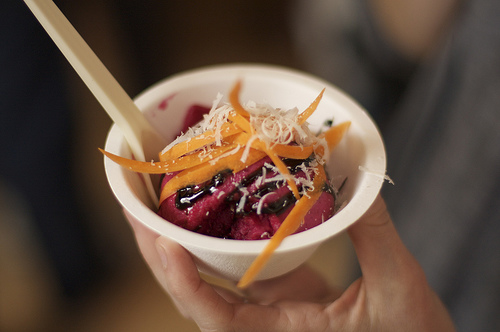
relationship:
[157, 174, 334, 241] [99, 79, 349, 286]
meat under carrots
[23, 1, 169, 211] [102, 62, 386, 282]
utensil on side of bowl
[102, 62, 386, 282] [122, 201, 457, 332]
bowl held by hand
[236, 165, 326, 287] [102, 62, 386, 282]
carrot piece hanging over bowl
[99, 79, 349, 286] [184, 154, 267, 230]
carrots are on top of strawberries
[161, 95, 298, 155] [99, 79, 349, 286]
cheese on top of carrots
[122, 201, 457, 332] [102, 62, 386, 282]
hand holding bowl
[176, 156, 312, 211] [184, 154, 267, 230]
jam on strawberries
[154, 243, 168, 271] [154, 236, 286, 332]
nail on finger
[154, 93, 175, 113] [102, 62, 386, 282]
stain on bowl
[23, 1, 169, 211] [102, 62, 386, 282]
utensil in bowl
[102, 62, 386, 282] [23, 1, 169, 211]
bowl with a utensil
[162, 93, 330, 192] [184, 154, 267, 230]
coconut on strawberries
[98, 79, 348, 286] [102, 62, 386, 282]
fruit in bowl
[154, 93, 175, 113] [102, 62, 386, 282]
stain in bowl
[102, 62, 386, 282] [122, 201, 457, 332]
bowl in hand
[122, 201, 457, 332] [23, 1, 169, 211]
hand holding utensil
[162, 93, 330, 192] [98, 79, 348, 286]
coconut on fruit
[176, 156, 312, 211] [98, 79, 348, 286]
jam on top of fruit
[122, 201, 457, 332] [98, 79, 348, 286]
hand holding fruit